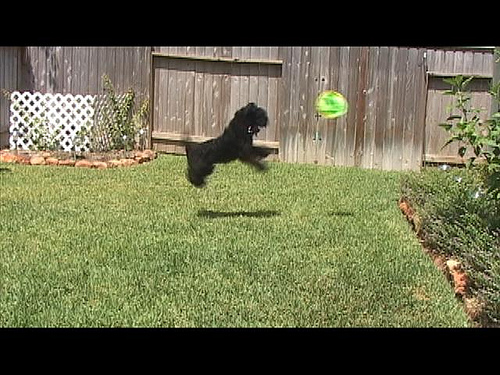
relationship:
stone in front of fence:
[144, 148, 158, 158] [0, 45, 498, 174]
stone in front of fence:
[119, 159, 140, 165] [0, 45, 498, 174]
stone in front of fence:
[73, 159, 106, 169] [0, 45, 498, 174]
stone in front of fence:
[41, 155, 60, 164] [0, 45, 498, 174]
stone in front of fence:
[0, 147, 17, 164] [0, 45, 498, 174]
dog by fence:
[181, 103, 271, 187] [0, 45, 498, 174]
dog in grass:
[181, 103, 271, 187] [0, 153, 474, 327]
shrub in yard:
[402, 168, 500, 295] [0, 122, 499, 329]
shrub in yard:
[402, 168, 472, 212] [0, 122, 499, 329]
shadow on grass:
[197, 209, 279, 217] [0, 153, 474, 327]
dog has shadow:
[181, 103, 271, 187] [197, 209, 279, 217]